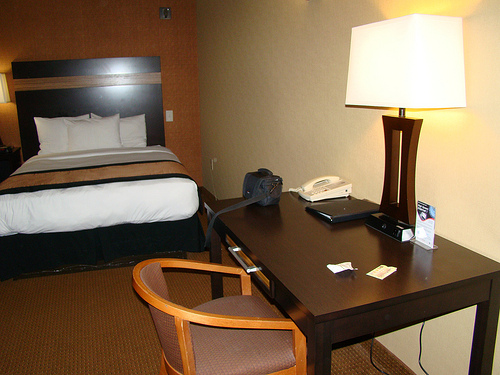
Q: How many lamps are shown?
A: 1.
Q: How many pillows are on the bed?
A: 3.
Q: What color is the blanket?
A: White.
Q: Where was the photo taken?
A: A hotel room.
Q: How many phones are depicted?
A: 1.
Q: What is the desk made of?
A: Wood.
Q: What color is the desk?
A: Brown.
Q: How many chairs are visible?
A: 1.